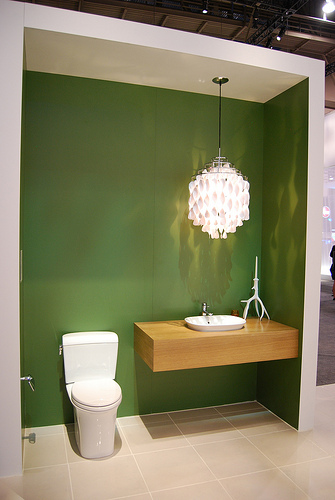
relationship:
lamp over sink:
[186, 75, 261, 253] [179, 315, 248, 332]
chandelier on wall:
[188, 159, 253, 240] [99, 154, 175, 245]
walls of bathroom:
[19, 69, 308, 428] [23, 68, 308, 497]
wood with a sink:
[160, 349, 178, 363] [179, 315, 248, 332]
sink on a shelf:
[179, 315, 248, 332] [133, 312, 301, 372]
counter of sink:
[140, 329, 287, 371] [169, 298, 249, 335]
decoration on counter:
[239, 255, 274, 322] [140, 329, 287, 371]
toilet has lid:
[63, 335, 125, 461] [71, 378, 121, 406]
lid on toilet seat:
[71, 378, 121, 406] [70, 393, 124, 411]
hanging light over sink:
[183, 73, 252, 241] [180, 299, 247, 335]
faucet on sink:
[199, 299, 216, 321] [183, 311, 247, 334]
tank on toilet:
[60, 332, 119, 380] [63, 335, 125, 461]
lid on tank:
[53, 323, 126, 346] [45, 309, 126, 387]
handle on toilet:
[59, 343, 63, 355] [63, 335, 125, 461]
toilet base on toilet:
[70, 406, 119, 459] [63, 335, 125, 461]